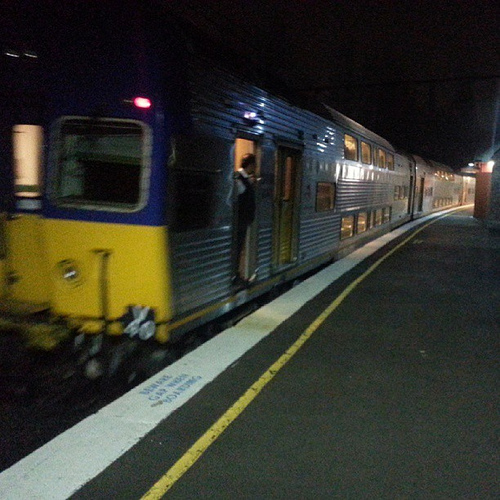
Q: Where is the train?
A: At the station.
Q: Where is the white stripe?
A: On the platform.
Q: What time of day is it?
A: The night.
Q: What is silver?
A: Side of the train.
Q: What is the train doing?
A: Parked.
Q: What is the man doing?
A: Standing.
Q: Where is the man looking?
A: To the right.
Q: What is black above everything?
A: The sky.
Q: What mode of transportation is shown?
A: Train.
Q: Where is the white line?
A: Beside the train.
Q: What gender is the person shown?
A: Male.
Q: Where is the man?
A: Train door.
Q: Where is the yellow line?
A: Next to the white line.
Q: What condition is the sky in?
A: Dark.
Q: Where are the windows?
A: Train.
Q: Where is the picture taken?
A: A railway.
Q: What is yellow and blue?
A: A train.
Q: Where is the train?
A: On the tracks.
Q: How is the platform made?
A: Of concrete.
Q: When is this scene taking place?
A: Night time.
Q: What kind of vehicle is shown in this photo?
A: Train.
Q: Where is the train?
A: Next to the platform.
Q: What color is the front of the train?
A: Blue and yellow.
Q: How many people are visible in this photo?
A: One.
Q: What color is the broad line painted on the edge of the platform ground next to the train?
A: White.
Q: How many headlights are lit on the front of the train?
A: One.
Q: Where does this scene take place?
A: Approaching a train stop.